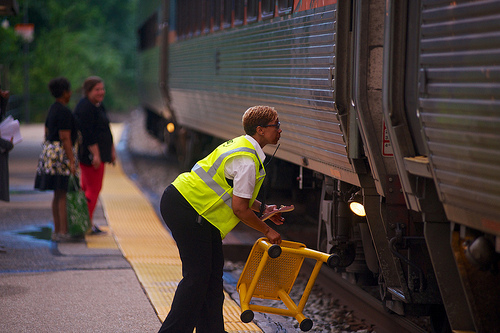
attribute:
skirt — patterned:
[28, 139, 78, 196]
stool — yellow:
[213, 197, 375, 332]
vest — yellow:
[173, 136, 280, 230]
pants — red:
[79, 161, 105, 231]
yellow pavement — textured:
[98, 164, 263, 331]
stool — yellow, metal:
[235, 236, 339, 331]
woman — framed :
[154, 84, 284, 324]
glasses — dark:
[265, 110, 285, 128]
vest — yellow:
[151, 136, 329, 296]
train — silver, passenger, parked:
[132, 0, 497, 331]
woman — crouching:
[133, 101, 327, 312]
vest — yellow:
[185, 76, 280, 237]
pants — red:
[79, 162, 106, 235]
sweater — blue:
[73, 95, 114, 161]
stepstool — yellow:
[236, 235, 328, 297]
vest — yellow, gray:
[168, 136, 268, 236]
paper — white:
[0, 121, 22, 148]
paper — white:
[2, 112, 13, 123]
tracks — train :
[271, 197, 427, 331]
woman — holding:
[154, 99, 289, 331]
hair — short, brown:
[217, 84, 289, 184]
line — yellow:
[105, 151, 197, 328]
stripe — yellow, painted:
[89, 157, 192, 331]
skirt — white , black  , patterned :
[41, 140, 77, 178]